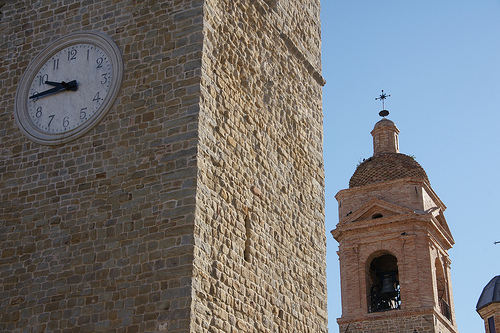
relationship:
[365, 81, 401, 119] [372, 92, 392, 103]
cross with lightning rod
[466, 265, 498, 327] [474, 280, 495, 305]
building with a roof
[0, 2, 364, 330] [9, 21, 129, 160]
brick wall with clock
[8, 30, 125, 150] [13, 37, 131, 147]
clock with clock face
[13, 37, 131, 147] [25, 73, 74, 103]
clock face and hands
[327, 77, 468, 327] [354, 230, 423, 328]
tower with window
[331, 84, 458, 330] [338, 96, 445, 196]
building with top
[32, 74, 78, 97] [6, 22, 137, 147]
hand of clock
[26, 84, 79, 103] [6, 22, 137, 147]
hand of clock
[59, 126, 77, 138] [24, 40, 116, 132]
stone ring around clock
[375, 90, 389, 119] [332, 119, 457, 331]
weather vane on tower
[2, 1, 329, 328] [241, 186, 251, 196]
clock tower made of brick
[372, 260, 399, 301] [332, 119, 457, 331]
bell in tower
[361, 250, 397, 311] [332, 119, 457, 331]
opening in tower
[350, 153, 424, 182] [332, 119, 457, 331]
roof on tower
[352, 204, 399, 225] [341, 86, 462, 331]
triangle on tower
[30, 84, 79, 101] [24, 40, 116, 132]
hand on clock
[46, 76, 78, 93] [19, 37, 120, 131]
hand on clock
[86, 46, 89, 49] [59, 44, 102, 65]
dots on top of numbers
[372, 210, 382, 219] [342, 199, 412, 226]
hole in triangle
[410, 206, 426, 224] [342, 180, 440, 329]
stones formed into wall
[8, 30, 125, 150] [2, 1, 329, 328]
clock on clock tower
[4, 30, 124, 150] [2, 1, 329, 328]
clock on clock tower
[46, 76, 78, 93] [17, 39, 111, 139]
hand on clock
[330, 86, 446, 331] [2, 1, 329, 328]
tower behind clock tower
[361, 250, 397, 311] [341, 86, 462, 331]
opening on tower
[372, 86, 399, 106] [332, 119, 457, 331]
lightning rod on top of tower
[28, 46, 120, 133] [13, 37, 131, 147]
english numerals on clock face